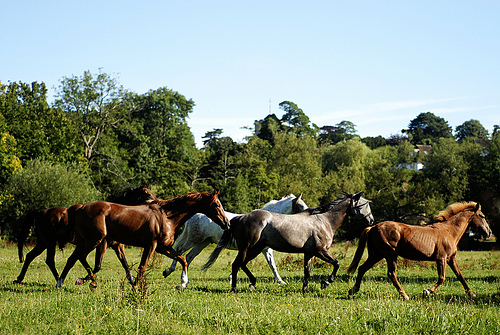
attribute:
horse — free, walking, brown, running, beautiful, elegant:
[344, 200, 493, 305]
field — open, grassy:
[3, 227, 497, 334]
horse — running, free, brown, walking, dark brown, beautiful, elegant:
[54, 187, 232, 301]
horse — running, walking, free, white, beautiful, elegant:
[162, 191, 310, 294]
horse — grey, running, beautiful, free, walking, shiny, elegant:
[202, 188, 376, 299]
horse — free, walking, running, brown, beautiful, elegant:
[13, 184, 160, 294]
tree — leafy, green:
[8, 157, 105, 265]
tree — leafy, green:
[215, 169, 253, 216]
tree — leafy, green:
[1, 130, 27, 204]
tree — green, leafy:
[274, 150, 324, 214]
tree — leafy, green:
[397, 175, 447, 223]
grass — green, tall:
[4, 245, 500, 334]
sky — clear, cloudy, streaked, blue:
[3, 1, 500, 148]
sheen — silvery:
[253, 209, 316, 248]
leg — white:
[163, 248, 190, 293]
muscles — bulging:
[152, 209, 178, 250]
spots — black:
[187, 216, 204, 245]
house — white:
[389, 143, 435, 171]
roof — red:
[415, 142, 434, 154]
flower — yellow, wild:
[103, 304, 116, 314]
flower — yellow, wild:
[277, 300, 297, 311]